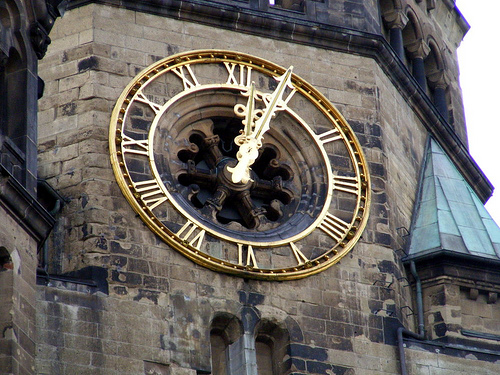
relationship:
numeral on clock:
[153, 53, 237, 95] [112, 55, 354, 259]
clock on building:
[112, 55, 354, 259] [60, 77, 88, 135]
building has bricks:
[60, 77, 88, 135] [370, 25, 396, 39]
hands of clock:
[233, 51, 288, 154] [112, 55, 354, 259]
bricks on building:
[370, 25, 396, 39] [60, 77, 88, 135]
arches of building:
[195, 286, 239, 366] [60, 77, 88, 135]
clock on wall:
[112, 55, 354, 259] [86, 309, 165, 351]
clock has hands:
[112, 55, 354, 259] [233, 51, 288, 154]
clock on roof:
[112, 55, 354, 259] [384, 122, 470, 254]